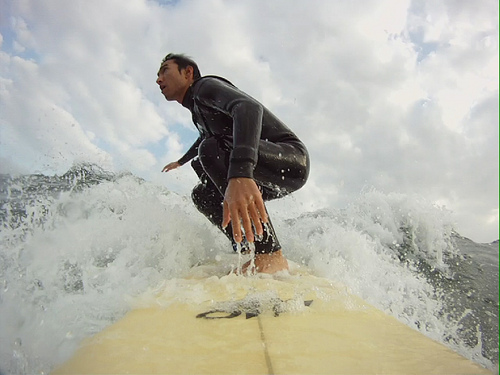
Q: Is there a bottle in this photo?
A: No, there are no bottles.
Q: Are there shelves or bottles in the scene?
A: No, there are no bottles or shelves.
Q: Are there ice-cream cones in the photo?
A: No, there are no ice-cream cones.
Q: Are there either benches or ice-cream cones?
A: No, there are no ice-cream cones or benches.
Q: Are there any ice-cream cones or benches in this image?
A: No, there are no ice-cream cones or benches.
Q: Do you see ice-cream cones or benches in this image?
A: No, there are no ice-cream cones or benches.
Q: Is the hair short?
A: Yes, the hair is short.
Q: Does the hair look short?
A: Yes, the hair is short.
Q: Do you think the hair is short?
A: Yes, the hair is short.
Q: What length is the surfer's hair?
A: The hair is short.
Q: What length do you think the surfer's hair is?
A: The hair is short.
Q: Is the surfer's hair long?
A: No, the hair is short.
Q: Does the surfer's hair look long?
A: No, the hair is short.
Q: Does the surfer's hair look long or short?
A: The hair is short.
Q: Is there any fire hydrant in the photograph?
A: No, there are no fire hydrants.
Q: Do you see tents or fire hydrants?
A: No, there are no fire hydrants or tents.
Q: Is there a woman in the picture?
A: No, there are no women.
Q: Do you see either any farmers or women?
A: No, there are no women or farmers.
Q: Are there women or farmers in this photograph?
A: No, there are no women or farmers.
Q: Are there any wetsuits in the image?
A: Yes, there is a wetsuit.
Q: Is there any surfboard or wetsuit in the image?
A: Yes, there is a wetsuit.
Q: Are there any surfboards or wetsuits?
A: Yes, there is a wetsuit.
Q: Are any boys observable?
A: No, there are no boys.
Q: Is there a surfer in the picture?
A: Yes, there is a surfer.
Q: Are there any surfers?
A: Yes, there is a surfer.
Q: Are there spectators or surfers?
A: Yes, there is a surfer.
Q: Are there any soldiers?
A: No, there are no soldiers.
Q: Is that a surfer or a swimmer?
A: That is a surfer.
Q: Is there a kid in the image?
A: No, there are no children.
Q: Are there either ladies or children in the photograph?
A: No, there are no children or ladies.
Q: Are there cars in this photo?
A: No, there are no cars.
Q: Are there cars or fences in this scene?
A: No, there are no cars or fences.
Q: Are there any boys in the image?
A: No, there are no boys.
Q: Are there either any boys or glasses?
A: No, there are no boys or glasses.